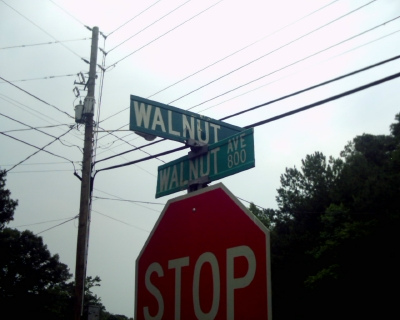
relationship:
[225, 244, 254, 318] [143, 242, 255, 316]
p in stop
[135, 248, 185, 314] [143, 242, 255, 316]
s in stop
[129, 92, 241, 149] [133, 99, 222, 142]
sign says walnut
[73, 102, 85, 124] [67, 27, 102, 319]
bucket up on electric pole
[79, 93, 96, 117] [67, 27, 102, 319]
bucket up on electric pole